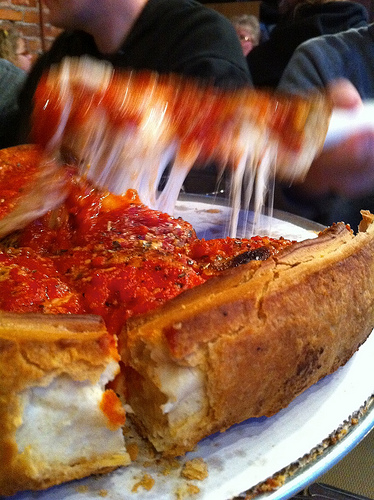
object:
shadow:
[196, 202, 258, 242]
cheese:
[18, 363, 126, 461]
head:
[233, 13, 261, 59]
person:
[230, 12, 261, 58]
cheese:
[160, 365, 204, 416]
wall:
[0, 0, 65, 78]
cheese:
[79, 118, 282, 236]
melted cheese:
[0, 145, 374, 500]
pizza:
[32, 57, 334, 185]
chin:
[46, 6, 70, 25]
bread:
[114, 208, 373, 461]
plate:
[12, 198, 373, 500]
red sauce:
[0, 138, 295, 324]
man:
[16, 0, 254, 197]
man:
[272, 25, 374, 236]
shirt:
[16, 0, 254, 193]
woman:
[0, 20, 34, 135]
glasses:
[17, 47, 30, 56]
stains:
[206, 452, 226, 474]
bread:
[0, 310, 137, 492]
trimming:
[175, 482, 200, 497]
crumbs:
[180, 456, 209, 482]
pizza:
[0, 59, 373, 498]